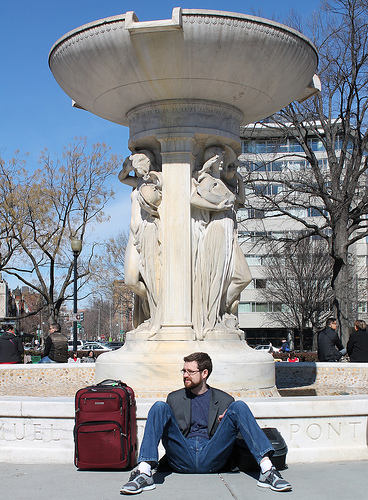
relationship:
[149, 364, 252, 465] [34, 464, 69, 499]
man on ground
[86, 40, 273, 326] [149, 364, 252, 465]
statue behind man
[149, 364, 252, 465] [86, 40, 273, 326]
man in front of statue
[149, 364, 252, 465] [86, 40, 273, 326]
man by statue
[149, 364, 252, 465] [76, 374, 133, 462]
man with luggage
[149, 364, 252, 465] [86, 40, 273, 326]
man near statue